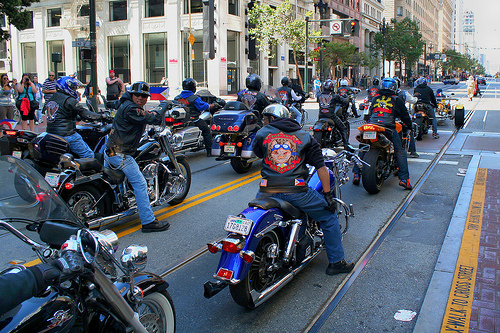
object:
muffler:
[249, 270, 296, 308]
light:
[237, 249, 258, 265]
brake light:
[220, 238, 242, 255]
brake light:
[362, 123, 379, 132]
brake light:
[5, 129, 15, 134]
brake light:
[313, 127, 322, 132]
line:
[407, 156, 459, 167]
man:
[249, 103, 355, 277]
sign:
[327, 20, 345, 37]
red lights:
[211, 266, 235, 279]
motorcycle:
[202, 147, 353, 308]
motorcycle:
[413, 102, 432, 142]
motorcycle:
[337, 92, 357, 119]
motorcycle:
[314, 114, 350, 150]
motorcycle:
[277, 94, 306, 124]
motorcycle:
[14, 97, 110, 204]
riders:
[252, 102, 356, 275]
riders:
[411, 76, 440, 138]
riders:
[339, 77, 358, 117]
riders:
[369, 73, 381, 113]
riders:
[274, 75, 305, 125]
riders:
[239, 73, 272, 122]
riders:
[177, 78, 216, 157]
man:
[43, 73, 111, 158]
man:
[173, 77, 216, 159]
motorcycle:
[351, 122, 412, 195]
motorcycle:
[211, 100, 276, 175]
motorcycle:
[168, 89, 226, 154]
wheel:
[226, 222, 285, 310]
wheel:
[158, 157, 193, 205]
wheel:
[363, 145, 391, 195]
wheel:
[228, 139, 254, 174]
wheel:
[44, 177, 121, 232]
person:
[350, 77, 411, 190]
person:
[101, 80, 172, 234]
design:
[260, 131, 300, 173]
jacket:
[41, 92, 106, 136]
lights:
[100, 228, 122, 250]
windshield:
[0, 158, 84, 230]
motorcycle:
[1, 153, 176, 331]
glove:
[62, 249, 87, 273]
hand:
[33, 248, 86, 285]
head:
[127, 81, 151, 107]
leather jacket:
[105, 97, 167, 157]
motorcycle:
[49, 124, 193, 233]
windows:
[145, 30, 167, 83]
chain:
[101, 150, 126, 170]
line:
[439, 167, 489, 332]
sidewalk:
[409, 154, 499, 332]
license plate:
[222, 214, 254, 235]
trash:
[393, 308, 417, 323]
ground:
[0, 75, 499, 333]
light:
[206, 242, 223, 255]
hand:
[321, 190, 339, 211]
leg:
[291, 186, 356, 264]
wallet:
[105, 150, 118, 156]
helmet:
[261, 103, 292, 122]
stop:
[2, 79, 496, 228]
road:
[0, 78, 500, 330]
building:
[0, 0, 317, 103]